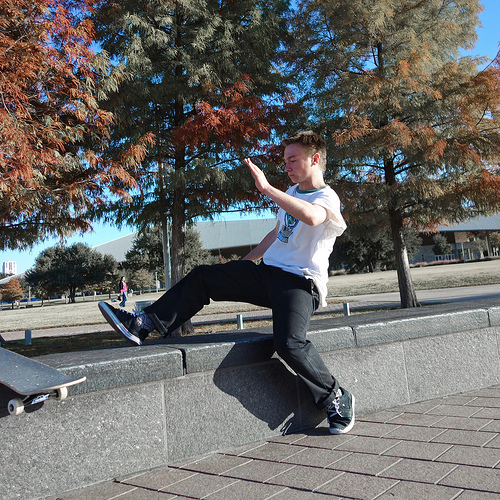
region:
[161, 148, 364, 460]
The boy is jumping over the step.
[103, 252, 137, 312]
Person standing in the field.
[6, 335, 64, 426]
Skateboard on the wall.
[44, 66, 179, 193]
The leaves on the tree is brown and green.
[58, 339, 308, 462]
The short wall is made of marble.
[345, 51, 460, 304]
The tree is tall.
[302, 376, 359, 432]
The man has on black sneakers.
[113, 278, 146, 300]
The girl has on pink shirt.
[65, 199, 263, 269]
The building in the background.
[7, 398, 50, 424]
The wheel is white.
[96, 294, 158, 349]
black and white sneakers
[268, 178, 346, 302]
the white color t shirt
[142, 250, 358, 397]
the black color pant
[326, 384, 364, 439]
the black color shoe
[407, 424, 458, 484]
the tiles on the floor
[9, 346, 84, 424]
the black color skating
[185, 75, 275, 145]
the red color leaves of the tree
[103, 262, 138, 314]
the women walking in the ground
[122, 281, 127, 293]
the pink color t shirt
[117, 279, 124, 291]
the black color jacket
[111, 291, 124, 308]
the black color hand bag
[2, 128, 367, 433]
Young man doing stunts with skateboard.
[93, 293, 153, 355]
Young man wearing black tennis shoes.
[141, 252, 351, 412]
Young man wearing black jeans.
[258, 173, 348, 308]
Young man dressed in white t-shirt with decal on front.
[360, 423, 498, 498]
Gray brown pavers on sidewalk.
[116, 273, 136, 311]
Woman walking down sidewalk in background.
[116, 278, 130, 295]
Woman wearing pink top and black sweater.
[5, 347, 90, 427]
Edge of skateboard on top of half wall.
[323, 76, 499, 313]
Pine trees growing in background.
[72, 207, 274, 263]
Top part of building in background.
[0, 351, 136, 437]
a skateboard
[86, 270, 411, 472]
black and white athletic sneakers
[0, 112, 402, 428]
a person skateboarding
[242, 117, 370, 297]
a man skateboarding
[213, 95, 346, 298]
a man wearing a white shirt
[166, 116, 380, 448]
a man wearing black pants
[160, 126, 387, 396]
a man wearing black jeans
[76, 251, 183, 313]
someone walking on the sidewalk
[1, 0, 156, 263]
trees with their leaves changing colors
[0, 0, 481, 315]
three trees